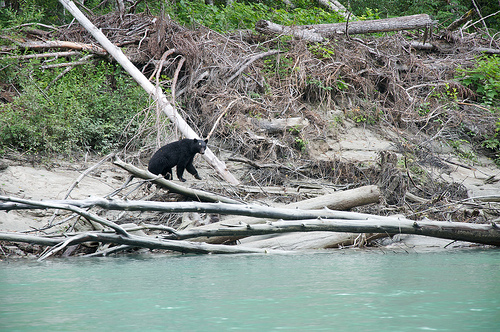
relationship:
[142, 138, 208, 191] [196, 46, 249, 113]
bear next to driftwood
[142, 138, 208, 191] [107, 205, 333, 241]
bear on river bank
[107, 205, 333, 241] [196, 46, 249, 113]
river bank has driftwood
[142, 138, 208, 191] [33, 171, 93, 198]
bear walking on beach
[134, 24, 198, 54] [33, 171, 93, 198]
trees on beach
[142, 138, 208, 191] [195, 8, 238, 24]
bear next to bush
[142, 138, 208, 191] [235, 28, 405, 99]
bear walking in debris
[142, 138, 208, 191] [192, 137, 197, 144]
bear has a ear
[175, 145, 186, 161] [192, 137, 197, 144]
bear has ear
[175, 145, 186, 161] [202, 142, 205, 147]
bear has a eye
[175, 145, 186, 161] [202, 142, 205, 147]
bear has eye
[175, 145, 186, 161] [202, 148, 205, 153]
bear has a nose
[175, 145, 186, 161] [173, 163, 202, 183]
bear has front legs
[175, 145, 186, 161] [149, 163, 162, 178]
bear has back legs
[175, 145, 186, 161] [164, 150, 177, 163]
bear has a body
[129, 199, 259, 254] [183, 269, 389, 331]
tree logs in water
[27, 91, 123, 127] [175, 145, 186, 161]
bushes behind bear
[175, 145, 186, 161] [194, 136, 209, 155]
bear has a head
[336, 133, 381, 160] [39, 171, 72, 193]
patch of dirt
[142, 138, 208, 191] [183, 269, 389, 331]
bear across water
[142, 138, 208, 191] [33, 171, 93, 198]
bear on beach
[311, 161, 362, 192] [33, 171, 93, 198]
tree limbs on beach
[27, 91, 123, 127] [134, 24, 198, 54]
bushes underneath trees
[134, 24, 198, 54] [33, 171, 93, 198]
trees are on beach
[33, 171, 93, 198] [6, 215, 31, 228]
beach has white sand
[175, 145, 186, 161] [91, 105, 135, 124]
bear sitting next to tree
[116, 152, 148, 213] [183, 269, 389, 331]
tree trunks by water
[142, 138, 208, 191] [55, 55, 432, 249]
bear in habitat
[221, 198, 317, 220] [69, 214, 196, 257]
logs on shoreline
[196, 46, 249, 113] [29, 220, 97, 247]
driftwood on ground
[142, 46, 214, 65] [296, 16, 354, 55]
tangle of vines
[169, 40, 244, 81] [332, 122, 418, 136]
branches washed ashore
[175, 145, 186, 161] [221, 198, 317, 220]
bear steps through logs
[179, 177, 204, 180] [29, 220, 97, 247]
feet on ground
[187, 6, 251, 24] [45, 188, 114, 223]
vegetation further away on shore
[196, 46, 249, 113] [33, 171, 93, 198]
driftwood on beach